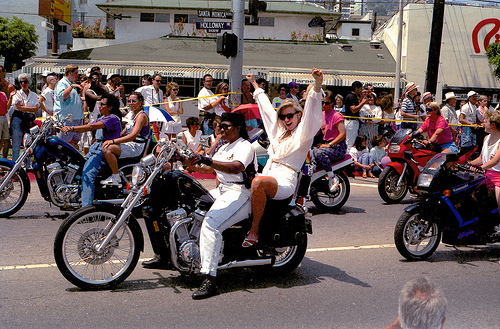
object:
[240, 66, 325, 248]
female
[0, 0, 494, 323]
parade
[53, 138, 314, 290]
motorcycle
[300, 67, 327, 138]
arms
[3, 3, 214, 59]
air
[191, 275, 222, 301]
feet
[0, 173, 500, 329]
ground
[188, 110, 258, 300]
driver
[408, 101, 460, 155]
lady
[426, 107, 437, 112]
sunglasses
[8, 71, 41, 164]
people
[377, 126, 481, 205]
motorcycle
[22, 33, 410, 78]
shops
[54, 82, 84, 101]
arms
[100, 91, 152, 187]
lady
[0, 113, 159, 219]
motorcycle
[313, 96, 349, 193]
women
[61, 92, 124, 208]
women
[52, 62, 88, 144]
man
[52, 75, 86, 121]
blue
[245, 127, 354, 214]
motorcycles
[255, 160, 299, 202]
white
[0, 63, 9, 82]
head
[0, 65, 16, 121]
man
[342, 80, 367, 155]
people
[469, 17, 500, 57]
writing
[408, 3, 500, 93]
wall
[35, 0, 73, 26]
sign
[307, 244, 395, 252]
line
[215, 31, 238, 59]
signal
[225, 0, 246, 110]
pole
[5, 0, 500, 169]
roadside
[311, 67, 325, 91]
hands